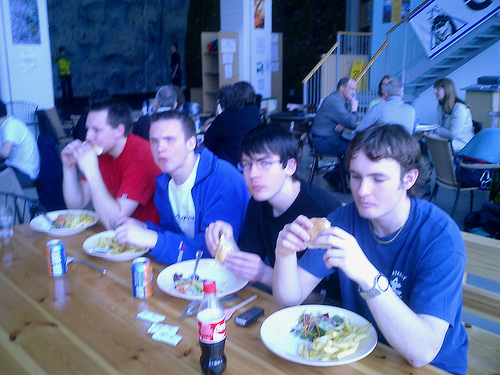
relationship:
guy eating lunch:
[61, 101, 159, 230] [29, 205, 102, 234]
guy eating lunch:
[147, 110, 245, 267] [82, 227, 158, 260]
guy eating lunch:
[233, 121, 333, 303] [154, 255, 252, 301]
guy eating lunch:
[329, 123, 467, 374] [257, 302, 379, 372]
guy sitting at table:
[61, 101, 159, 230] [1, 210, 448, 373]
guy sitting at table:
[147, 110, 245, 267] [1, 210, 448, 373]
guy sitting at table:
[233, 121, 333, 303] [1, 210, 448, 373]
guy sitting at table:
[329, 123, 467, 374] [1, 210, 448, 373]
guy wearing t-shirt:
[61, 101, 159, 230] [82, 135, 162, 225]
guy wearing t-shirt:
[147, 110, 245, 267] [166, 177, 205, 238]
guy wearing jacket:
[147, 110, 245, 267] [153, 170, 248, 251]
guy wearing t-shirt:
[233, 121, 333, 303] [247, 193, 339, 296]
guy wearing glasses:
[233, 121, 333, 303] [236, 157, 294, 169]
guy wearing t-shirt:
[329, 123, 467, 374] [327, 199, 465, 373]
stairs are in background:
[302, 1, 499, 132] [1, 0, 498, 136]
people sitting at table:
[312, 77, 474, 153] [341, 124, 446, 142]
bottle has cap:
[196, 279, 228, 373] [202, 280, 220, 293]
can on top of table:
[42, 238, 71, 279] [1, 210, 448, 373]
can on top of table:
[129, 256, 154, 300] [1, 210, 448, 373]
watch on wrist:
[357, 274, 388, 301] [355, 261, 375, 283]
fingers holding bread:
[316, 228, 349, 247] [304, 217, 333, 251]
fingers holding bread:
[283, 214, 308, 253] [304, 217, 333, 251]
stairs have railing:
[302, 1, 499, 132] [302, 22, 371, 83]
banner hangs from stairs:
[407, 0, 499, 58] [302, 1, 499, 132]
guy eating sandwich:
[61, 101, 159, 230] [75, 142, 103, 157]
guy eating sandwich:
[329, 123, 467, 374] [304, 217, 333, 251]